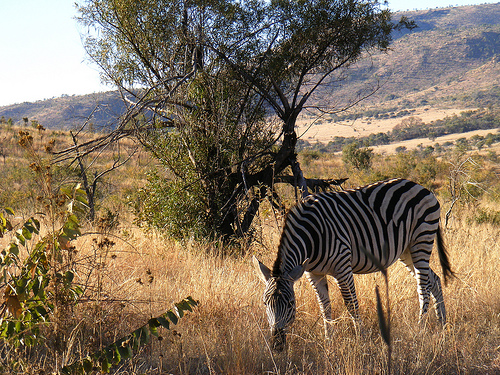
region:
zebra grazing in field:
[242, 172, 465, 347]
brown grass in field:
[158, 252, 240, 294]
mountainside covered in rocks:
[408, 0, 498, 91]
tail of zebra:
[433, 221, 455, 286]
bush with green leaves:
[130, 168, 208, 238]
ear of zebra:
[250, 253, 272, 285]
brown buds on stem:
[14, 121, 64, 248]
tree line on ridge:
[391, 114, 496, 136]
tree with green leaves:
[95, 0, 405, 83]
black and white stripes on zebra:
[344, 192, 406, 249]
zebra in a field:
[244, 169, 487, 364]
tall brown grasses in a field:
[158, 242, 238, 294]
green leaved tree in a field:
[82, 2, 412, 137]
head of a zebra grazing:
[246, 254, 333, 361]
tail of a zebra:
[428, 221, 476, 291]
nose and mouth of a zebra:
[265, 327, 295, 357]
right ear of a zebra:
[240, 253, 274, 287]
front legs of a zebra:
[309, 274, 375, 349]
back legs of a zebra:
[394, 249, 456, 330]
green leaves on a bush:
[160, 289, 203, 324]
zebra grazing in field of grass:
[249, 177, 478, 358]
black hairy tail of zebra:
[429, 220, 460, 288]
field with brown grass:
[161, 245, 251, 300]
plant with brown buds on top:
[19, 121, 66, 250]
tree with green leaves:
[141, 1, 384, 159]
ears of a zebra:
[243, 248, 313, 287]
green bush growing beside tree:
[135, 174, 215, 244]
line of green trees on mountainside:
[373, 103, 498, 142]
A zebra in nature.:
[232, 173, 479, 359]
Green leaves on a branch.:
[100, 293, 201, 361]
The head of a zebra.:
[235, 245, 316, 356]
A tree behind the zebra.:
[80, 1, 387, 251]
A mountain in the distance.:
[241, 2, 496, 113]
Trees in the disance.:
[307, 105, 493, 150]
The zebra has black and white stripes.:
[345, 195, 422, 246]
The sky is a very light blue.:
[15, 18, 71, 81]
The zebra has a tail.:
[430, 217, 460, 287]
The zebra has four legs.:
[311, 246, 453, 335]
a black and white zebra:
[252, 179, 456, 358]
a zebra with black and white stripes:
[249, 177, 454, 354]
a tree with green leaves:
[70, 4, 420, 255]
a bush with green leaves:
[0, 129, 202, 371]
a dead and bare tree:
[441, 150, 490, 230]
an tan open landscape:
[1, 4, 498, 371]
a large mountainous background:
[1, 6, 498, 153]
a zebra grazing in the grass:
[249, 179, 459, 351]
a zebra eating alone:
[251, 177, 455, 351]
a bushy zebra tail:
[436, 226, 458, 286]